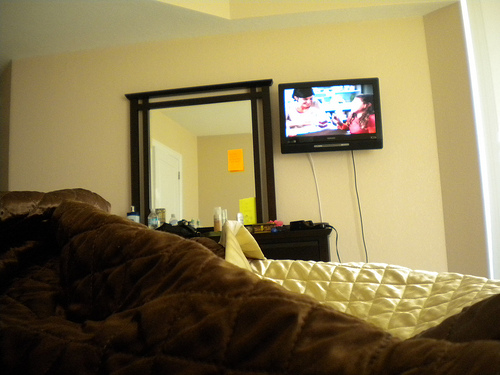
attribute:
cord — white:
[303, 151, 328, 228]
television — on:
[278, 78, 383, 153]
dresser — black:
[150, 210, 343, 263]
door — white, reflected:
[148, 143, 186, 223]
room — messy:
[2, 2, 494, 374]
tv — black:
[277, 79, 383, 151]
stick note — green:
[235, 193, 257, 227]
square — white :
[382, 265, 411, 287]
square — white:
[330, 265, 360, 285]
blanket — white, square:
[213, 216, 497, 338]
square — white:
[367, 298, 399, 314]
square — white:
[446, 287, 478, 312]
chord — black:
[350, 150, 369, 265]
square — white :
[332, 284, 354, 302]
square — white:
[423, 291, 452, 306]